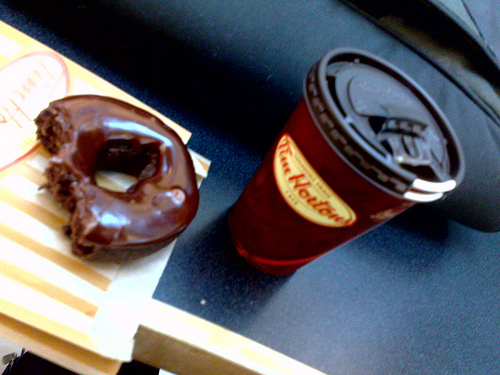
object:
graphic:
[0, 50, 70, 174]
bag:
[0, 17, 213, 375]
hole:
[93, 136, 161, 193]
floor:
[395, 275, 495, 346]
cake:
[34, 94, 199, 263]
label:
[272, 132, 359, 228]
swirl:
[236, 246, 335, 267]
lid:
[304, 46, 467, 203]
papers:
[14, 265, 136, 315]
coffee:
[226, 96, 418, 276]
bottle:
[226, 45, 466, 278]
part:
[403, 178, 456, 203]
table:
[57, 11, 497, 373]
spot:
[200, 299, 206, 305]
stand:
[0, 12, 499, 375]